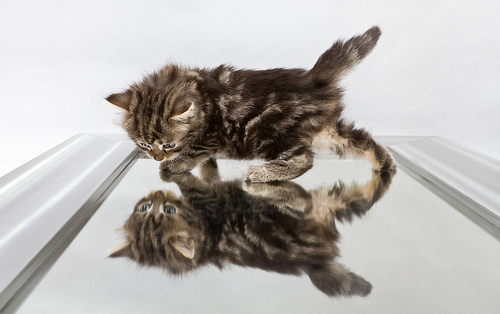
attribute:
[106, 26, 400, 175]
cat — striped, young, furry, small, cute, grey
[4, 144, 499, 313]
mirror — wooden, glass, smooth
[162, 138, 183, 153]
eye — blue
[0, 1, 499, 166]
wall — white